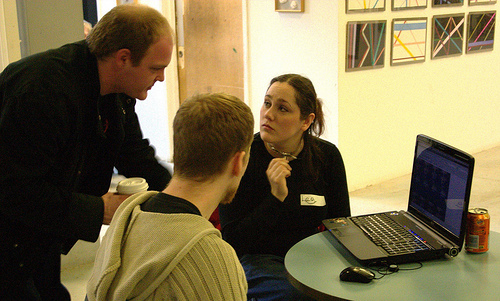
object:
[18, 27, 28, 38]
plate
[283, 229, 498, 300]
table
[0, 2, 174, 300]
man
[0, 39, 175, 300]
coat